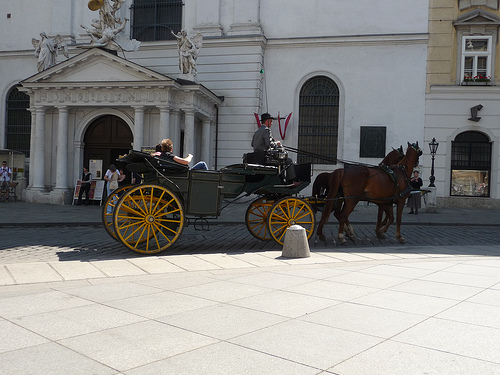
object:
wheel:
[115, 179, 188, 255]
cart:
[100, 149, 317, 254]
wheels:
[100, 185, 186, 255]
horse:
[310, 136, 422, 243]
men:
[149, 137, 211, 172]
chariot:
[230, 139, 425, 247]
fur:
[356, 171, 386, 194]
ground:
[0, 269, 499, 373]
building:
[0, 31, 218, 207]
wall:
[344, 41, 422, 125]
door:
[447, 127, 492, 202]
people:
[149, 137, 209, 173]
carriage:
[100, 140, 423, 255]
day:
[0, 0, 499, 374]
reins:
[287, 144, 352, 164]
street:
[0, 242, 499, 374]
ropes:
[287, 145, 371, 166]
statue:
[170, 26, 205, 83]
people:
[77, 164, 96, 202]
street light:
[424, 134, 440, 188]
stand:
[423, 186, 438, 211]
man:
[103, 160, 121, 216]